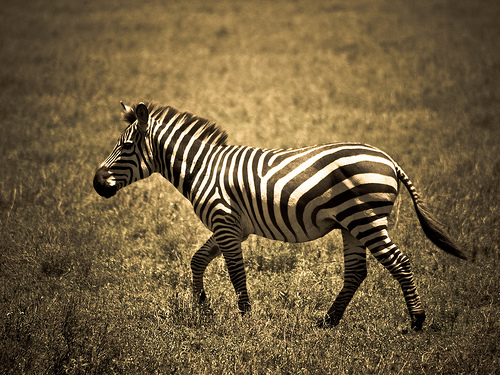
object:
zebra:
[94, 99, 470, 335]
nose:
[90, 168, 107, 184]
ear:
[133, 102, 153, 120]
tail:
[400, 164, 476, 261]